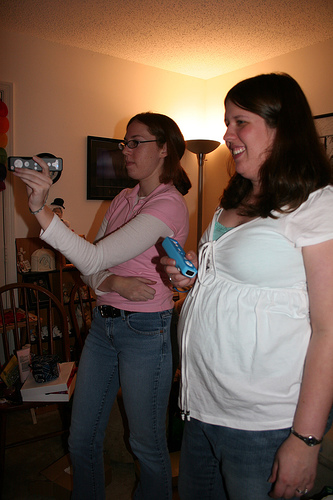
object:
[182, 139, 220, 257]
floor lamp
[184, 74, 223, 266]
corner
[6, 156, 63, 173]
wiimote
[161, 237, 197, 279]
wiimote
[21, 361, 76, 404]
cardboard box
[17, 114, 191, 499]
girl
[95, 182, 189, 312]
shirt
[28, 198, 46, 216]
bracelet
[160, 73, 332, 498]
woman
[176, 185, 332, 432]
shirt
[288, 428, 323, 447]
watch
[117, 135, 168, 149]
glasses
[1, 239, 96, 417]
shelves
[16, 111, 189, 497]
women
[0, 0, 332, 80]
ceiling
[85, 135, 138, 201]
picture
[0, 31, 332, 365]
wall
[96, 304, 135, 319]
belt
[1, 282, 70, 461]
chair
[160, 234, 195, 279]
wiimotes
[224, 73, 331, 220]
hair